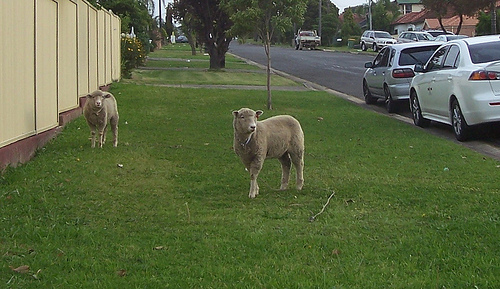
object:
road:
[227, 35, 377, 100]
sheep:
[81, 90, 120, 149]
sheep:
[231, 107, 304, 200]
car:
[408, 33, 500, 142]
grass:
[0, 41, 500, 288]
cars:
[360, 30, 398, 52]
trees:
[173, 0, 258, 72]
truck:
[294, 27, 322, 51]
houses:
[358, 0, 500, 38]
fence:
[1, 0, 122, 174]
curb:
[295, 76, 307, 87]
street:
[221, 39, 499, 156]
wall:
[0, 0, 122, 175]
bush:
[121, 34, 151, 80]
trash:
[345, 37, 357, 50]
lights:
[470, 68, 496, 85]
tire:
[410, 91, 431, 128]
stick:
[308, 191, 335, 223]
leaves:
[78, 155, 127, 176]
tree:
[222, 1, 310, 111]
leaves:
[236, 13, 255, 25]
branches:
[233, 5, 271, 41]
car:
[361, 41, 446, 113]